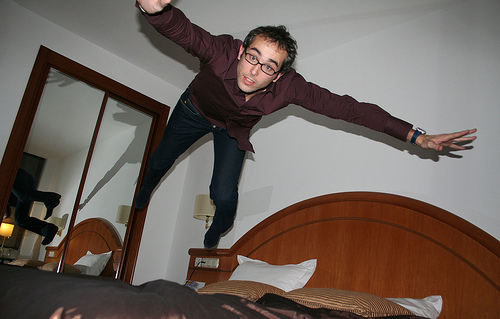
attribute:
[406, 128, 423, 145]
wristwatch — black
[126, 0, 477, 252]
man — jumping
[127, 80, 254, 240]
jeans — dark blue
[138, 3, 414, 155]
shirt — collared, maroon, dark red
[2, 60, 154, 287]
mirror — reflective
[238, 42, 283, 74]
glasses — dark-rimmed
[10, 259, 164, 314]
sheets — dark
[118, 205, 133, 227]
lampshade — beige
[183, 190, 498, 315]
headboard — brown, wooden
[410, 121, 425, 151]
watch — black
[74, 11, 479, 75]
ceiling — white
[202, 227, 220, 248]
sock — black, dress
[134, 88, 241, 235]
jeans — dark